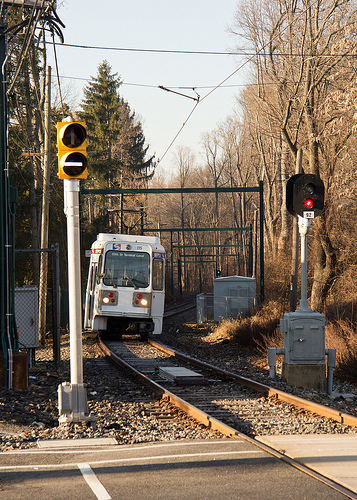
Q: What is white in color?
A: A train.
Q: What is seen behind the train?
A: A tall tree.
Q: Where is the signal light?
A: Side of the track.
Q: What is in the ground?
A: Gravel.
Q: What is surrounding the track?
A: A large number of trees.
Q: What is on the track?
A: A train.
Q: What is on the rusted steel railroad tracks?
A: White train.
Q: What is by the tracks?
A: Tall brown trees.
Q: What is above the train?
A: Electric lines.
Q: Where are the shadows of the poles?
A: On road.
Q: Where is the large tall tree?
A: In front of the train.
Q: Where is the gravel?
A: On the ground.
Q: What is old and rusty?
A: The train tracks.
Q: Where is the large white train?
A: On the train tracks.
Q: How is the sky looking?
A: Clear.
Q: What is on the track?
A: Shadow.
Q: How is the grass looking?
A: High.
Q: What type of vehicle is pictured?
A: Train.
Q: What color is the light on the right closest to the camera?
A: Red.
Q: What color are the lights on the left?
A: White.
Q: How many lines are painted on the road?
A: Three.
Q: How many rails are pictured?
A: Two.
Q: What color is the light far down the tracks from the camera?
A: Green.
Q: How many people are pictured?
A: None.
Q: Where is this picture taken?
A: Next to a train track.